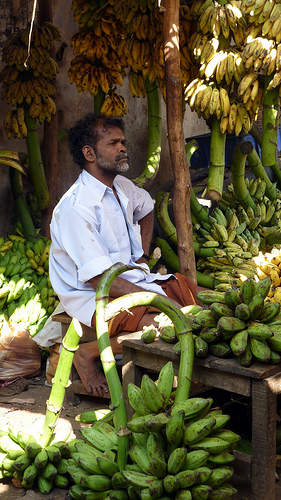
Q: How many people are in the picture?
A: One.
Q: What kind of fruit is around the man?
A: Bananas.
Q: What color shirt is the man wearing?
A: White.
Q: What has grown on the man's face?
A: A beard.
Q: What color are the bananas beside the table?
A: Green.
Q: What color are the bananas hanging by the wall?
A: Yellow.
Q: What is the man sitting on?
A: A bench.